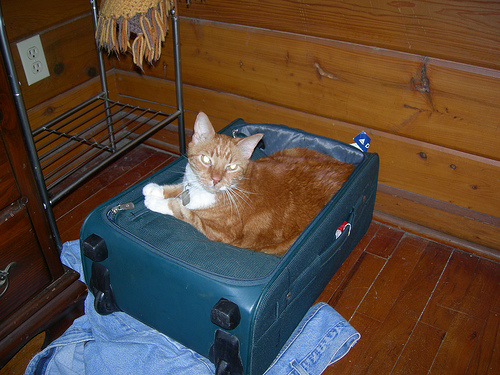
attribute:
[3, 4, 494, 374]
picture — cat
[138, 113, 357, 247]
cat — orange, white, brown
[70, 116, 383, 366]
suitcase — blue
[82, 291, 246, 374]
wheels — black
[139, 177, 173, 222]
paws — white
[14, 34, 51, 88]
outlet — electrical, white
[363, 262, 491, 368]
floor — wood, cherry wood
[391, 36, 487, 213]
wall — wood, wooden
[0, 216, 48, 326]
drawer — brown, wood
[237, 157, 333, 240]
fur — brown, orange, red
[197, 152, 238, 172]
eyes — bright, shiny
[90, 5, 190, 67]
object — cloth, knitted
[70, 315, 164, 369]
cloth — blue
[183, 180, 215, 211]
chest — white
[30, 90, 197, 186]
shelf — metal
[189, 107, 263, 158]
ears — pointy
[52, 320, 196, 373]
jeans — blue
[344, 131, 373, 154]
tag — white, blue